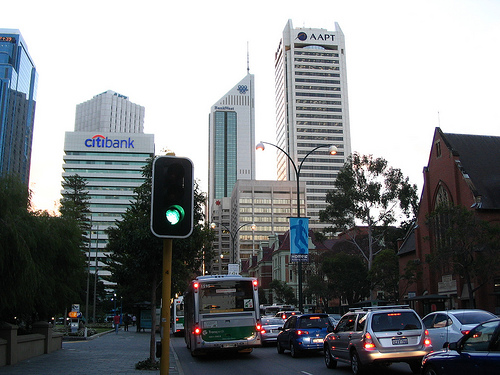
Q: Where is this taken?
A: Downtown in a city.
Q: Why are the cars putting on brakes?
A: To stop or slow down.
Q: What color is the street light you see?
A: It is green.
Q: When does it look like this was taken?
A: In the early evening.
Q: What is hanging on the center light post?
A: A flag.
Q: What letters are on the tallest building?
A: AAPT.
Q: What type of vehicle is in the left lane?
A: A bus.